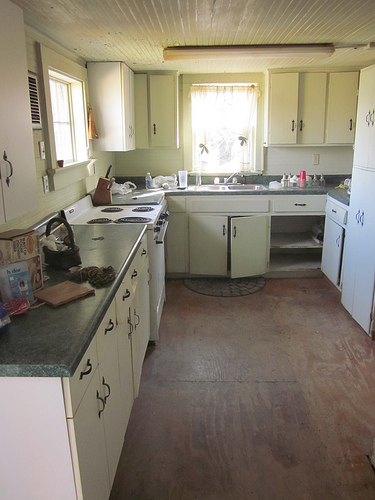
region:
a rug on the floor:
[182, 277, 273, 296]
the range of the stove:
[81, 201, 168, 225]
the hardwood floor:
[107, 268, 371, 498]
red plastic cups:
[298, 169, 309, 187]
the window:
[189, 85, 258, 171]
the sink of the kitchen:
[190, 181, 268, 190]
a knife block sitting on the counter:
[94, 162, 120, 205]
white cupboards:
[166, 193, 346, 279]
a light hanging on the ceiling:
[162, 46, 348, 63]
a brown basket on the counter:
[40, 213, 83, 266]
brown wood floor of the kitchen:
[220, 335, 355, 411]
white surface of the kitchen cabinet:
[24, 415, 72, 468]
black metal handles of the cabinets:
[96, 375, 114, 415]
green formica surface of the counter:
[39, 316, 72, 356]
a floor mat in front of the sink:
[184, 273, 265, 297]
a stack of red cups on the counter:
[294, 169, 311, 189]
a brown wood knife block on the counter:
[92, 169, 118, 204]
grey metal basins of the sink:
[199, 184, 265, 190]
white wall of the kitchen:
[149, 153, 175, 166]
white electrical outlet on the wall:
[40, 174, 52, 194]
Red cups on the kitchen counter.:
[294, 167, 308, 188]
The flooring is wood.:
[182, 308, 333, 485]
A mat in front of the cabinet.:
[181, 274, 275, 300]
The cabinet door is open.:
[201, 210, 271, 278]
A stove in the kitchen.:
[77, 193, 167, 232]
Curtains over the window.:
[187, 86, 272, 176]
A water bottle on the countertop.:
[142, 167, 156, 190]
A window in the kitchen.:
[46, 62, 93, 161]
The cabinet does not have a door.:
[278, 226, 321, 273]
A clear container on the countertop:
[178, 168, 195, 189]